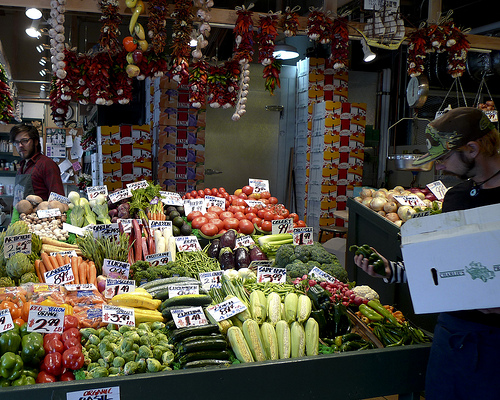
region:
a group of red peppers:
[45, 333, 70, 378]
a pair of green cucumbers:
[182, 337, 224, 352]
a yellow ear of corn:
[245, 320, 268, 359]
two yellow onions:
[372, 195, 397, 210]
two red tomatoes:
[200, 214, 222, 235]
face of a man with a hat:
[416, 106, 488, 181]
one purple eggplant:
[220, 248, 234, 268]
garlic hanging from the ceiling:
[238, 60, 248, 112]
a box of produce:
[98, 125, 153, 143]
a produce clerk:
[11, 124, 60, 191]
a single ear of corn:
[244, 316, 266, 365]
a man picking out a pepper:
[350, 107, 499, 382]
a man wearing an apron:
[1, 126, 67, 226]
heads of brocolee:
[272, 236, 339, 285]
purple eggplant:
[214, 229, 265, 266]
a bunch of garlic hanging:
[231, 56, 253, 123]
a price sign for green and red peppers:
[23, 300, 67, 336]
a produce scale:
[381, 75, 441, 174]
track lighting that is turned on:
[23, 4, 51, 98]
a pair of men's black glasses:
[10, 134, 34, 147]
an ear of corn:
[226, 323, 252, 363]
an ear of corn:
[240, 317, 263, 358]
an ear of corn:
[261, 320, 280, 359]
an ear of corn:
[276, 320, 290, 361]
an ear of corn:
[290, 320, 304, 358]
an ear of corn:
[304, 315, 320, 355]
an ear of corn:
[295, 290, 308, 323]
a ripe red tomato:
[237, 220, 252, 234]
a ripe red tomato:
[223, 215, 238, 230]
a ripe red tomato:
[199, 223, 217, 235]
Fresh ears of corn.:
[217, 290, 322, 362]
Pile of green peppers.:
[0, 321, 42, 388]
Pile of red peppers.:
[37, 316, 84, 383]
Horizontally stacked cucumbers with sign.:
[152, 277, 233, 369]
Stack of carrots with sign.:
[32, 247, 100, 289]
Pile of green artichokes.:
[0, 221, 41, 287]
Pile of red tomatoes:
[170, 185, 230, 202]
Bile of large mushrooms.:
[12, 190, 67, 218]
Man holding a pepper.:
[344, 107, 497, 397]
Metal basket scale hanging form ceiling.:
[382, 64, 437, 176]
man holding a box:
[387, 69, 491, 341]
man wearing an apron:
[5, 108, 48, 234]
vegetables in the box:
[1, 181, 454, 391]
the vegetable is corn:
[192, 272, 314, 370]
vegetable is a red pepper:
[14, 299, 106, 396]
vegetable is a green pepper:
[1, 318, 51, 399]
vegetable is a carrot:
[26, 241, 107, 290]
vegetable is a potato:
[0, 183, 69, 225]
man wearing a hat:
[408, 96, 493, 175]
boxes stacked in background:
[278, 48, 398, 312]